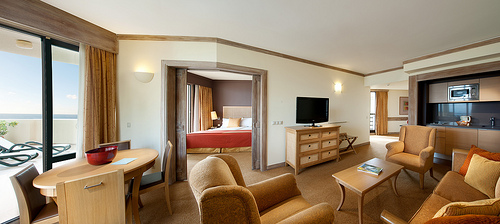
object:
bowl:
[87, 147, 119, 164]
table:
[35, 144, 160, 220]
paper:
[111, 155, 140, 168]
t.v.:
[294, 95, 332, 126]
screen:
[302, 98, 325, 121]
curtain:
[89, 49, 120, 147]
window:
[1, 36, 44, 172]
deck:
[7, 119, 100, 164]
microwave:
[448, 85, 477, 99]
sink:
[435, 119, 469, 129]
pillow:
[464, 143, 499, 177]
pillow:
[467, 155, 497, 192]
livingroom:
[211, 80, 467, 206]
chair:
[55, 170, 137, 224]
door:
[43, 43, 88, 161]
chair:
[195, 153, 337, 224]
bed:
[184, 106, 250, 153]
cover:
[195, 127, 248, 149]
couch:
[407, 148, 500, 224]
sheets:
[221, 132, 262, 149]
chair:
[141, 140, 179, 214]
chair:
[94, 140, 132, 162]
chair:
[11, 164, 60, 221]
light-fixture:
[331, 77, 347, 94]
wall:
[261, 59, 393, 113]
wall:
[427, 72, 487, 109]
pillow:
[221, 117, 239, 129]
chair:
[6, 138, 69, 159]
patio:
[10, 102, 94, 195]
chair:
[0, 141, 38, 166]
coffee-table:
[341, 158, 406, 223]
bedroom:
[183, 77, 260, 156]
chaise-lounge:
[3, 138, 64, 166]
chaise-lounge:
[6, 151, 34, 163]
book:
[360, 163, 380, 175]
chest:
[292, 127, 337, 172]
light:
[129, 69, 157, 84]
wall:
[118, 52, 172, 139]